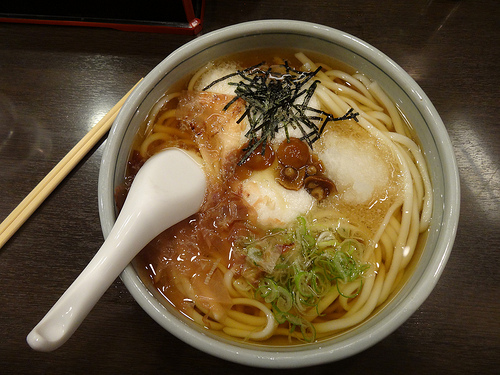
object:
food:
[114, 47, 434, 351]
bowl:
[97, 18, 463, 368]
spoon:
[26, 146, 206, 353]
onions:
[233, 215, 371, 344]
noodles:
[320, 77, 368, 108]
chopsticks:
[0, 76, 145, 248]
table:
[1, 1, 498, 374]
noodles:
[217, 302, 271, 338]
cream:
[317, 131, 389, 203]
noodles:
[395, 132, 422, 260]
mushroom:
[276, 137, 310, 167]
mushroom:
[274, 164, 306, 191]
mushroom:
[304, 175, 338, 203]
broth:
[140, 250, 158, 271]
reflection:
[0, 96, 54, 179]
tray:
[1, 1, 201, 35]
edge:
[0, 18, 203, 34]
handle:
[25, 248, 142, 352]